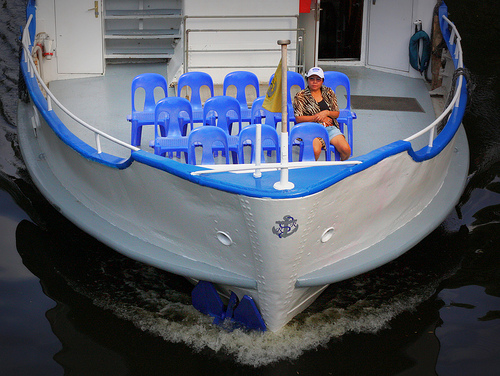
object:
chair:
[177, 71, 213, 136]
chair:
[153, 96, 193, 165]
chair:
[222, 71, 259, 136]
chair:
[237, 123, 280, 164]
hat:
[304, 67, 325, 79]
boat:
[18, 0, 471, 334]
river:
[0, 0, 500, 376]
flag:
[261, 59, 282, 113]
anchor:
[190, 280, 266, 334]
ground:
[378, 125, 420, 141]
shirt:
[292, 84, 339, 129]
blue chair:
[125, 72, 170, 146]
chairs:
[126, 71, 357, 165]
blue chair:
[287, 121, 331, 162]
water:
[0, 0, 499, 374]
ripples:
[52, 256, 469, 367]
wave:
[0, 0, 500, 376]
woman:
[292, 67, 350, 162]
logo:
[272, 215, 298, 239]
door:
[318, 1, 365, 64]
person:
[293, 67, 351, 161]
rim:
[18, 0, 466, 200]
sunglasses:
[309, 76, 321, 81]